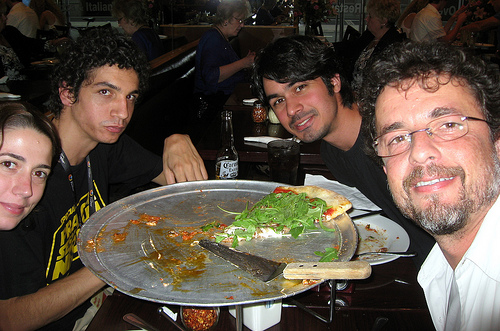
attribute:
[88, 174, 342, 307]
pan — metal, silver, round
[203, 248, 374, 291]
spatula — silver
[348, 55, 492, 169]
hair — curly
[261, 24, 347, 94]
hair — dark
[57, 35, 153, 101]
hair — curly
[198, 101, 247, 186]
bottle — glass, clear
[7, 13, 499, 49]
people — eating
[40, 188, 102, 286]
writing — yellow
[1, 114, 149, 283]
shirt — yellow, black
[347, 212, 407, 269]
plate — white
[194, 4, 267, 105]
woman — eating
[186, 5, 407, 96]
women — talking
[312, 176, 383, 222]
napkins — white